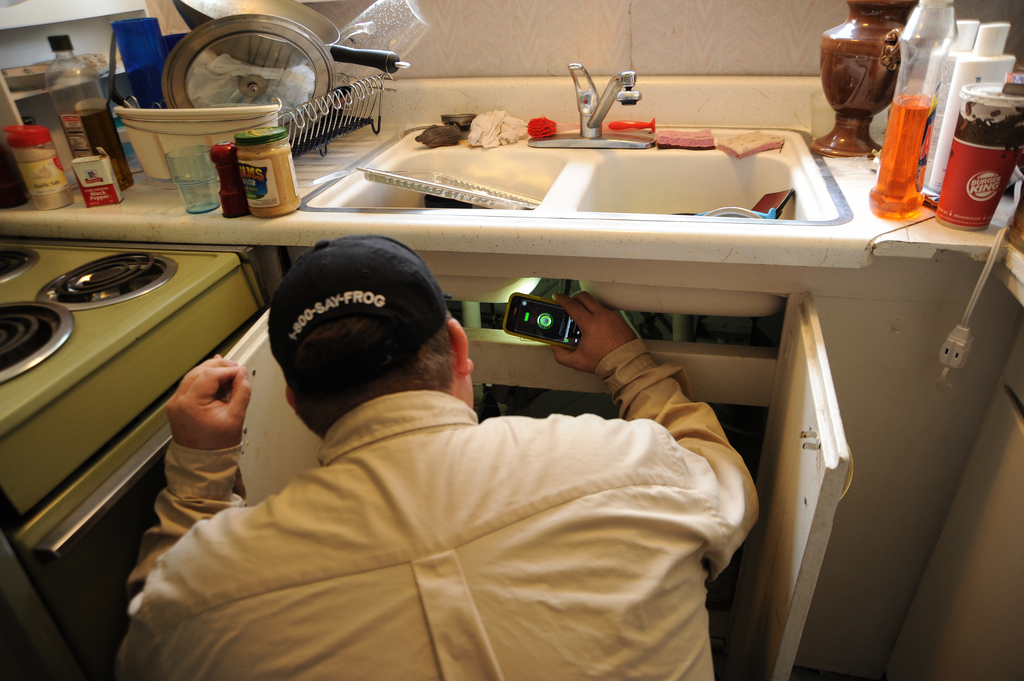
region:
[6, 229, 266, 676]
A stove in a kitchen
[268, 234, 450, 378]
A hat on a man's head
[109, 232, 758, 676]
A man looking under a sink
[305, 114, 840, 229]
A sink in a kitchen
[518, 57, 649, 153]
A faucet in a kitchen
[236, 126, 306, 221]
A jar on the counter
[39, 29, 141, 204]
A bottle on the counter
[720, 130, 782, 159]
A spong on a sink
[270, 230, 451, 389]
the hat is black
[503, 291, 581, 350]
the phone has lights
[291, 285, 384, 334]
the numbers and letters are white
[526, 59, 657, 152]
the water fixture is silver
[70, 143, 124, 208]
the spice container is red and white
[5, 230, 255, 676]
the stove is green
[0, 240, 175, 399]
the burners are black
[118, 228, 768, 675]
the man is holding the phone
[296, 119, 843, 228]
the double sink is white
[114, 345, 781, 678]
white shirt on man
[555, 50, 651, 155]
sink spout that's silver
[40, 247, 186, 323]
one stove burner that's electric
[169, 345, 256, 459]
chubby male hand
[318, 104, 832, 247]
double white sink basin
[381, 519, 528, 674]
pleat on a shirt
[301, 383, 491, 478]
collar on a white shirt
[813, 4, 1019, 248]
items on the right side of a kitchen counter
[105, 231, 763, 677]
man wearing black cap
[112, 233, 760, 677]
man using a cellphone to look under a sink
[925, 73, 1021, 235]
paper disposable burger kind cup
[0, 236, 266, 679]
old green stove and oven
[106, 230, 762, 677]
man wearing black cap and beige shirt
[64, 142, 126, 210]
white and red canister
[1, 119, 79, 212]
plastic spice container with red lid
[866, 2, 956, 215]
plastic bottle of orange dish soap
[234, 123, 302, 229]
jar on the counter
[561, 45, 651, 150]
faucet on the sink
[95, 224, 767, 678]
man taking a picture with cellphone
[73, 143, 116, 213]
black pepper container on the counter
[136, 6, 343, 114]
skillet in the strainer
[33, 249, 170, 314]
burner on the stove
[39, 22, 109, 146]
bottle on the counter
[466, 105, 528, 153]
wash cloth on the sink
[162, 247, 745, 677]
A man looking under a sink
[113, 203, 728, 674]
A man holding a cellphone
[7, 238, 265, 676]
green stove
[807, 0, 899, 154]
Brown vase near sink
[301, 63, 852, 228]
sink with dirty dishes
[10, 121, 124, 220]
spices sitting on counter